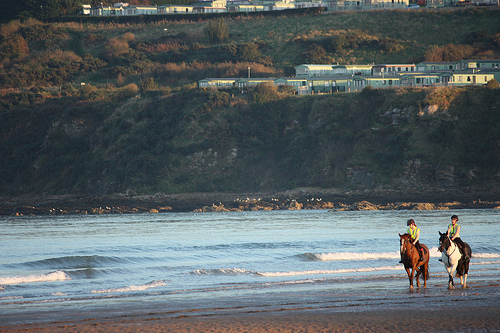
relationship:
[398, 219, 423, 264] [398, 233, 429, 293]
lady riding horse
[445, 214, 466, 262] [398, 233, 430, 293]
lady riding horse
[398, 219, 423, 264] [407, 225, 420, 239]
lady wearing shirt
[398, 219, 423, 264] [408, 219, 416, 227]
lady has helmet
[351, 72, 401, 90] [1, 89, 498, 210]
building on hill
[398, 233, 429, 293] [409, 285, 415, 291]
horse has hoove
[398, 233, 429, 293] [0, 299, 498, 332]
horse on beach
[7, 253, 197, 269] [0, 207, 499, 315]
wave in ocean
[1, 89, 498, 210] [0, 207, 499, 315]
hill behind ocean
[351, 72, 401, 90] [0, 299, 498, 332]
building near beach